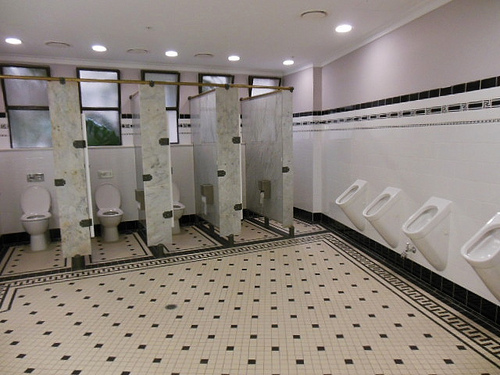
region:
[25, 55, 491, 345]
A men's bathroom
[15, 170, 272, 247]
Four kemode style toilets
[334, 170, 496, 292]
Four flush free urinals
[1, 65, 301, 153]
Five windows above the kemodes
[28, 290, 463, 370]
Off white with black tile floor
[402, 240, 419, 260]
Spigot for cleaning the bathroom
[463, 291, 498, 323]
Black time surrounding the whole bathroom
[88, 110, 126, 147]
A bush you can see through the window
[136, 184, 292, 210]
Three toilet paper dispensers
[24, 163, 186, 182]
Three toilet barrier dispesnors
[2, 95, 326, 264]
several bathroom stalls are open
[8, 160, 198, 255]
three white pocelin toilets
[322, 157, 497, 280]
four urinals on the wall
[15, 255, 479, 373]
a black and white tile floor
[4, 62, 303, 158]
windows above each toilet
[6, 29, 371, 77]
lights recessed in the ceiling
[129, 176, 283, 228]
toilet paper holders on walls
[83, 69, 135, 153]
one window is open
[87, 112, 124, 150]
something green in the window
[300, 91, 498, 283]
white and black tile on the wall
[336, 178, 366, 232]
white ceramic urinal bowl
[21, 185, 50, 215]
white plastic toilet lid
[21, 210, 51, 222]
white plastic toilet seat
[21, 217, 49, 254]
white ceramic toilet bowl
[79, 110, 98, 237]
white toilet stall door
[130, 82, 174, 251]
grey marble bathroom stall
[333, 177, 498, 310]
white urinals on wall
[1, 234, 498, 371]
black and white floor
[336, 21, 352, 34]
recessed light in ceiling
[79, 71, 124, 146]
glass window in wall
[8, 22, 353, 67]
recessed lights in ceiling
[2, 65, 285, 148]
row of windows on wall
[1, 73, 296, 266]
stalls with open doors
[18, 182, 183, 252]
toilets with covers up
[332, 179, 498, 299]
row of urinals on wall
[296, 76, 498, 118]
line of black tiles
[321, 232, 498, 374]
decorative tiles on floor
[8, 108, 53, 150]
frosted glass of window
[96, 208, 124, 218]
seat on toilet bowl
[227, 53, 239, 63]
round glowing white light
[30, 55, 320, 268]
public bathroom with stalls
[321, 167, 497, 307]
public bathroom with urinals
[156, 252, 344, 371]
black and white tile floor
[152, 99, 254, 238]
stalls have doors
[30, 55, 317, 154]
mens bathroom has windows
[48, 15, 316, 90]
lights are on in the bathroom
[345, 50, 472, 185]
the walls are white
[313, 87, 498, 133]
black stripe on the walls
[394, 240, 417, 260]
silver water line on wall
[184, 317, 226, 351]
black square tiles